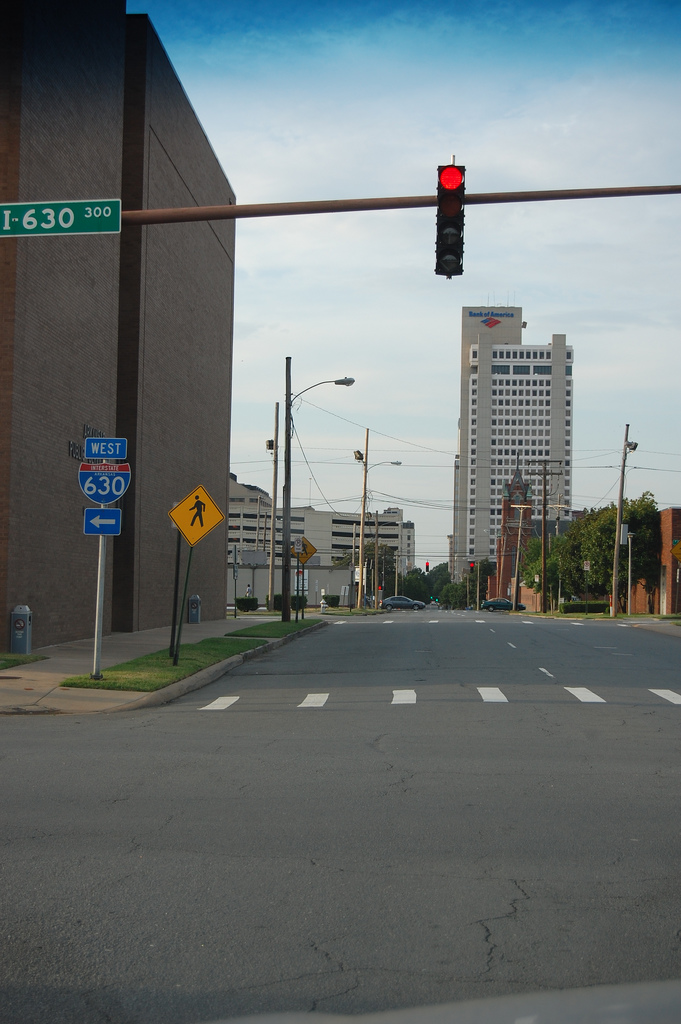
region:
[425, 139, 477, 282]
red light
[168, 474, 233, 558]
yellow sign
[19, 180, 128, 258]
green and white sign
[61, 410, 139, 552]
blue and white sign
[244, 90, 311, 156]
white clouds in the blue sky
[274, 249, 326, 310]
white clouds in the blue sky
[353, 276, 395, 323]
white clouds in the blue sky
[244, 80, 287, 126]
white clouds in the blue sky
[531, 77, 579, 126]
white clouds in the blue sky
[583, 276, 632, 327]
white clouds in the blue sky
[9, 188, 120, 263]
white and green sign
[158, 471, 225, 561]
yellow and black sign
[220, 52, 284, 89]
white clouds in the blue sky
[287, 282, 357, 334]
white clouds in the blue sky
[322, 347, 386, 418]
white clouds in the blue sky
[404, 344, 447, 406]
white clouds in the blue sky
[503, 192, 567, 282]
white clouds in the blue sky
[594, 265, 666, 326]
white clouds in the blue sky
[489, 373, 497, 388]
a window on a building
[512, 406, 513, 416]
a window on a building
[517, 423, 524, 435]
a window on a building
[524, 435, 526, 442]
indow on a building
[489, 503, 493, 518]
a window on a building a window on a building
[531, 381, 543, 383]
a window on a building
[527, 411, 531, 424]
a window on a building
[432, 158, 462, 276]
Traffic lamp with four lights showing red light.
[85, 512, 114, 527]
White arrow on blue sign.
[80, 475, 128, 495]
The number '630' written on a blue sign.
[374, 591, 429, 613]
Grey car with black tires.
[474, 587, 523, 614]
Green car with a black tire.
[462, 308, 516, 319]
Blue letters on a large grey building.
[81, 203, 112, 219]
The number 300 written in white on a green sign.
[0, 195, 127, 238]
Green and white sign hanging from pole.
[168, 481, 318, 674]
Two yellow and black signs on poles.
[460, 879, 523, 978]
dark colored crack on cement ground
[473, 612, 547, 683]
white dashed lines in center of the street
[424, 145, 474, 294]
glowing red light on traffic signal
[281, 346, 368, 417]
silver street light on side of road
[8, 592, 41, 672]
grey colored trash containers on sidewalk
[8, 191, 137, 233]
green street sign on metal pole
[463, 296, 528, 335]
bank of america logo on top of building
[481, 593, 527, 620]
green colored car driving a few blocks away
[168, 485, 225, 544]
yellow sign on green post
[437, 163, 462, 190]
red light on traffic light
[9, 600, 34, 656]
grey garbage can next to building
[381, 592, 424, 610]
grey car driving through intersection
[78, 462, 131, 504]
interstate sign on silver post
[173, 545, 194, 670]
crooked green sign post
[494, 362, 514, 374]
window on light grey building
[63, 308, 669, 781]
a scene downtown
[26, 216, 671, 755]
a scene during the daytime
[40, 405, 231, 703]
a couple of street signs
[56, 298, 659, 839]
a scene outside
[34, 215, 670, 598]
buildings in the area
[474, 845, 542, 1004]
a crack in cement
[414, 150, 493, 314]
a red traffic light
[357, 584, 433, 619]
a blue car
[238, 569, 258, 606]
a person walking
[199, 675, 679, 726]
pedestrian walkway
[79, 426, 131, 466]
WEST is written on the road sign